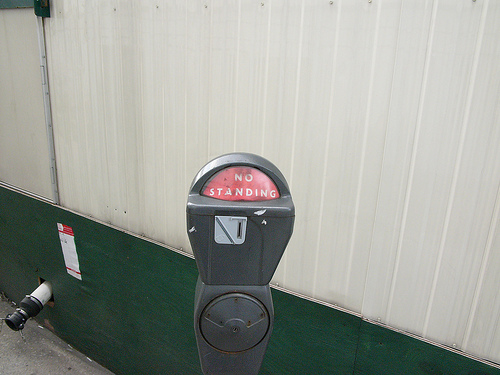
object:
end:
[3, 278, 54, 334]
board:
[0, 189, 497, 373]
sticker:
[47, 215, 85, 287]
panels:
[56, 15, 495, 325]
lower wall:
[0, 185, 200, 373]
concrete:
[5, 326, 101, 373]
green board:
[13, 202, 478, 372]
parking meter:
[184, 152, 295, 372]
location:
[196, 290, 274, 354]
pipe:
[31, 7, 68, 209]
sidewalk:
[11, 340, 63, 370]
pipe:
[3, 274, 59, 344]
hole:
[38, 270, 61, 310]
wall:
[29, 33, 498, 314]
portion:
[20, 224, 205, 351]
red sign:
[199, 162, 279, 202]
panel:
[196, 208, 272, 285]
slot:
[234, 213, 249, 239]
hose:
[3, 278, 52, 333]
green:
[92, 277, 162, 329]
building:
[0, 0, 493, 364]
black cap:
[2, 300, 42, 332]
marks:
[254, 207, 271, 226]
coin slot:
[214, 216, 246, 245]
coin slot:
[236, 221, 244, 240]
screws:
[54, 0, 479, 13]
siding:
[1, 0, 496, 364]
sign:
[56, 223, 84, 283]